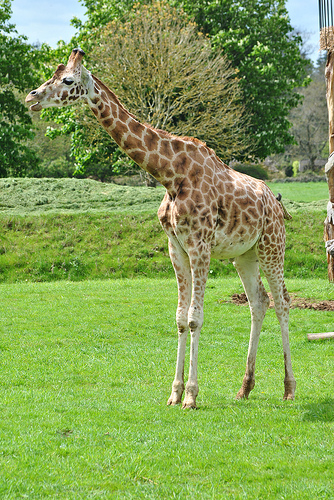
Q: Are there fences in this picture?
A: No, there are no fences.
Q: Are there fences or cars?
A: No, there are no fences or cars.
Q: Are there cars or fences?
A: No, there are no fences or cars.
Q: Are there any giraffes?
A: Yes, there is a giraffe.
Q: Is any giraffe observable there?
A: Yes, there is a giraffe.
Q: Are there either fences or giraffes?
A: Yes, there is a giraffe.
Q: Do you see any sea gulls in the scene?
A: No, there are no sea gulls.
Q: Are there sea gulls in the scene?
A: No, there are no sea gulls.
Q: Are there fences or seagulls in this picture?
A: No, there are no seagulls or fences.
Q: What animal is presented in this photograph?
A: The animal is a giraffe.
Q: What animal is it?
A: The animal is a giraffe.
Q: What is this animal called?
A: This is a giraffe.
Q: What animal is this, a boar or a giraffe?
A: This is a giraffe.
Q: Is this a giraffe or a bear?
A: This is a giraffe.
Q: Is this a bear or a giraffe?
A: This is a giraffe.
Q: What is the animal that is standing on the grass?
A: The animal is a giraffe.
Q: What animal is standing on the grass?
A: The animal is a giraffe.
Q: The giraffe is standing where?
A: The giraffe is standing on the grass.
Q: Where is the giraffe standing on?
A: The giraffe is standing on the grass.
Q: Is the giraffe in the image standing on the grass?
A: Yes, the giraffe is standing on the grass.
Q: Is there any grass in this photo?
A: Yes, there is grass.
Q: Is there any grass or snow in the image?
A: Yes, there is grass.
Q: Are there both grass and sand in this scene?
A: No, there is grass but no sand.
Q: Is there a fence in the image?
A: No, there are no fences.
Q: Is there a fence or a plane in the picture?
A: No, there are no fences or airplanes.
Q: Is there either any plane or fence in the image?
A: No, there are no fences or airplanes.